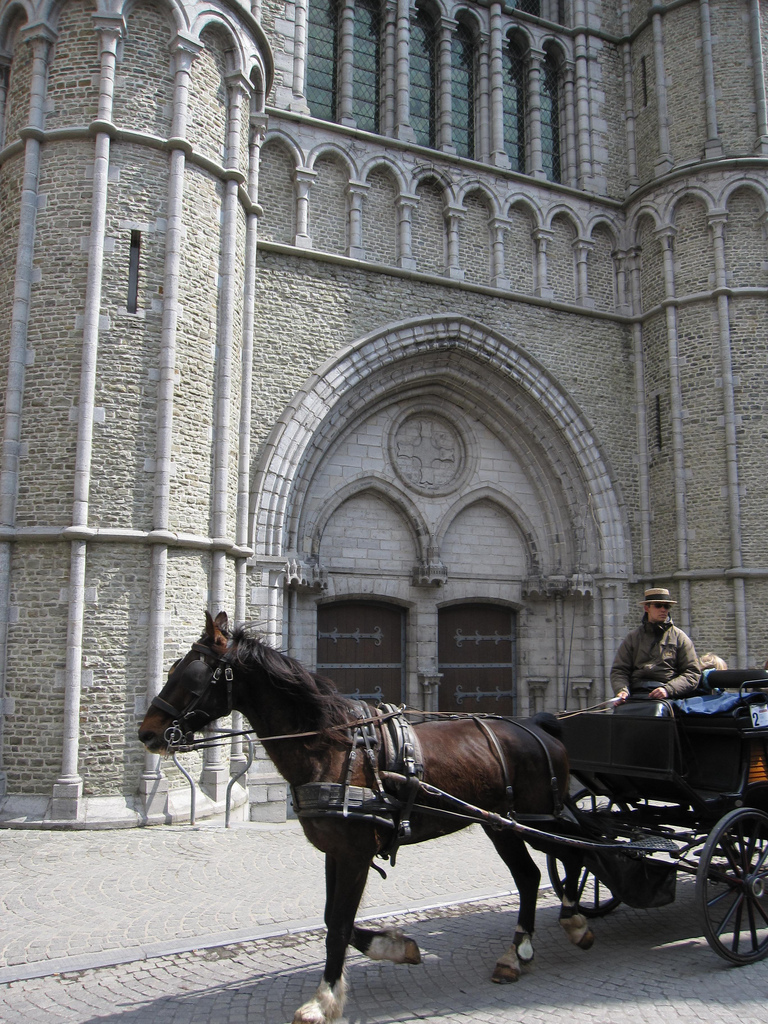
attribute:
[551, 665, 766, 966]
carriage — black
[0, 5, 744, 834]
building — stone